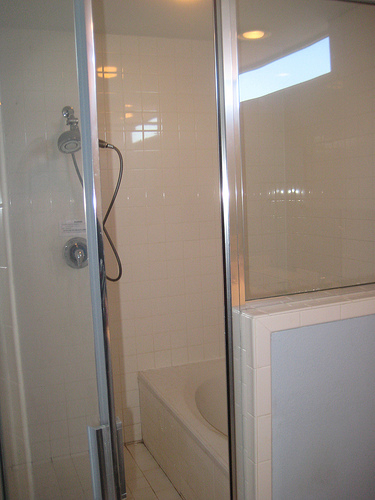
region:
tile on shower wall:
[141, 112, 160, 132]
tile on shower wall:
[151, 331, 170, 351]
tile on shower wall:
[128, 226, 145, 244]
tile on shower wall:
[122, 112, 142, 132]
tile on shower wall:
[168, 328, 186, 347]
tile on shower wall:
[176, 130, 194, 149]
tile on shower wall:
[186, 326, 203, 345]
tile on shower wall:
[177, 328, 201, 343]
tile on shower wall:
[188, 344, 200, 363]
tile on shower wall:
[170, 349, 189, 365]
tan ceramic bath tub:
[137, 357, 230, 498]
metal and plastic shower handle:
[64, 236, 89, 268]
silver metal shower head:
[59, 105, 87, 156]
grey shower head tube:
[70, 138, 123, 281]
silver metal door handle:
[87, 424, 115, 499]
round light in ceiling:
[241, 28, 264, 41]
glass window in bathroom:
[238, 33, 333, 102]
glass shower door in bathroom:
[2, 1, 123, 498]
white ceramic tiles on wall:
[97, 31, 221, 368]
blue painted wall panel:
[261, 309, 373, 498]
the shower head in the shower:
[55, 127, 85, 161]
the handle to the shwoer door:
[89, 412, 130, 497]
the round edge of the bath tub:
[190, 365, 230, 440]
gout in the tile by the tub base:
[125, 440, 179, 499]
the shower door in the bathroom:
[11, 17, 116, 495]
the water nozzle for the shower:
[70, 249, 83, 267]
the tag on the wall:
[60, 211, 91, 238]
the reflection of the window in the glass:
[223, 35, 343, 130]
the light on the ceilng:
[237, 23, 270, 46]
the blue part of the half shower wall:
[267, 311, 369, 497]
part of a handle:
[84, 439, 104, 469]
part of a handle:
[169, 447, 195, 492]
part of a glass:
[166, 366, 186, 401]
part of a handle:
[81, 425, 105, 464]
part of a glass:
[157, 431, 189, 482]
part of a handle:
[84, 429, 95, 461]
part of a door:
[160, 356, 186, 398]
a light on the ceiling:
[236, 22, 275, 52]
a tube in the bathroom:
[141, 351, 222, 490]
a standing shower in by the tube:
[42, 105, 132, 489]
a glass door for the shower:
[7, 131, 112, 493]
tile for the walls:
[240, 315, 270, 467]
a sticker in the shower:
[52, 207, 82, 237]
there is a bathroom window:
[240, 39, 335, 103]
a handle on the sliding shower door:
[64, 409, 120, 494]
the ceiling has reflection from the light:
[122, 0, 193, 60]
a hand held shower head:
[86, 124, 134, 306]